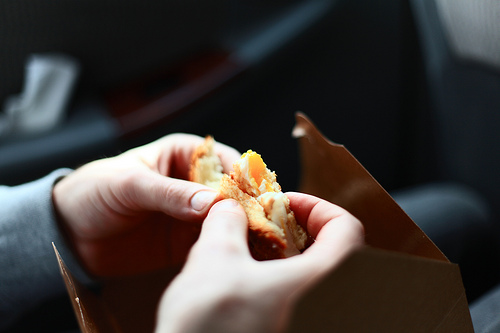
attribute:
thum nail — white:
[188, 186, 222, 216]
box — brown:
[261, 126, 473, 327]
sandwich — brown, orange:
[158, 129, 310, 259]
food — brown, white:
[176, 108, 309, 252]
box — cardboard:
[46, 110, 478, 331]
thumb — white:
[185, 191, 257, 271]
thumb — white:
[200, 197, 247, 262]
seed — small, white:
[267, 239, 286, 249]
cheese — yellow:
[248, 155, 258, 176]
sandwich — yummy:
[164, 127, 329, 267]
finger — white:
[154, 193, 302, 330]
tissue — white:
[2, 54, 74, 139]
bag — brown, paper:
[51, 112, 475, 332]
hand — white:
[74, 113, 194, 227]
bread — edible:
[190, 137, 303, 257]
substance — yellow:
[239, 143, 276, 193]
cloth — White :
[4, 47, 81, 132]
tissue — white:
[13, 52, 76, 136]